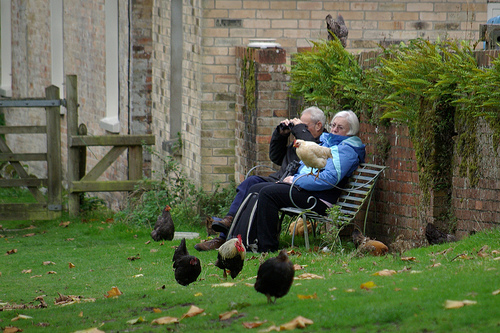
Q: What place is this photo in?
A: It is at the farm.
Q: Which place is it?
A: It is a farm.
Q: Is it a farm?
A: Yes, it is a farm.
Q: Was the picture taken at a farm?
A: Yes, it was taken in a farm.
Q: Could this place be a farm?
A: Yes, it is a farm.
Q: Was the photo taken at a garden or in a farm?
A: It was taken at a farm.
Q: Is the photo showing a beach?
A: No, the picture is showing a farm.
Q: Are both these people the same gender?
A: No, they are both male and female.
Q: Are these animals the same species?
A: Yes, all the animals are chicken.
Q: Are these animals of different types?
A: No, all the animals are chicken.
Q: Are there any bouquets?
A: No, there are no bouquets.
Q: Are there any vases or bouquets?
A: No, there are no bouquets or vases.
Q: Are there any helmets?
A: No, there are no helmets.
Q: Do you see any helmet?
A: No, there are no helmets.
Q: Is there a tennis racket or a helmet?
A: No, there are no helmets or rackets.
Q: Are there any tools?
A: No, there are no tools.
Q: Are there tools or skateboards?
A: No, there are no tools or skateboards.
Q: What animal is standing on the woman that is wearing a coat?
A: The chicken is standing on the woman.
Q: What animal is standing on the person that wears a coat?
A: The chicken is standing on the woman.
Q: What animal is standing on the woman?
A: The chicken is standing on the woman.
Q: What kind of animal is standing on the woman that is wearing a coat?
A: The animal is chicken.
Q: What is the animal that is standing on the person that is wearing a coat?
A: The animal is chicken.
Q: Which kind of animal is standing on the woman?
A: The animal is chicken.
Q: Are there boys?
A: No, there are no boys.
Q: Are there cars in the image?
A: No, there are no cars.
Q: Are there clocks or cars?
A: No, there are no cars or clocks.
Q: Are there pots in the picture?
A: No, there are no pots.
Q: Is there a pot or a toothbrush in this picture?
A: No, there are no pots or toothbrushes.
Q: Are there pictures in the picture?
A: No, there are no pictures.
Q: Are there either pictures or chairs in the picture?
A: No, there are no pictures or chairs.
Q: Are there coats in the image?
A: Yes, there is a coat.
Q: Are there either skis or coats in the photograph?
A: Yes, there is a coat.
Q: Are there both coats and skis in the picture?
A: No, there is a coat but no skis.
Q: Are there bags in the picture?
A: No, there are no bags.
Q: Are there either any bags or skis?
A: No, there are no bags or skis.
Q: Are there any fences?
A: Yes, there is a fence.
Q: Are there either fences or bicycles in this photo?
A: Yes, there is a fence.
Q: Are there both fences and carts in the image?
A: No, there is a fence but no carts.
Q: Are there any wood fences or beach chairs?
A: Yes, there is a wood fence.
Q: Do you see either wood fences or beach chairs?
A: Yes, there is a wood fence.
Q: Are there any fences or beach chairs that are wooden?
A: Yes, the fence is wooden.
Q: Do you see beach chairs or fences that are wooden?
A: Yes, the fence is wooden.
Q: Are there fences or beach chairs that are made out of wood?
A: Yes, the fence is made of wood.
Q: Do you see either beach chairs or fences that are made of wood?
A: Yes, the fence is made of wood.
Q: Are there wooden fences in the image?
A: Yes, there is a wood fence.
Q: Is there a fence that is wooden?
A: Yes, there is a fence that is wooden.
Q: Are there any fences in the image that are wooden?
A: Yes, there is a fence that is wooden.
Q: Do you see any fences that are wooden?
A: Yes, there is a fence that is wooden.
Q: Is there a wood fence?
A: Yes, there is a fence that is made of wood.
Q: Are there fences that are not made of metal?
A: Yes, there is a fence that is made of wood.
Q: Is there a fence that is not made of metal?
A: Yes, there is a fence that is made of wood.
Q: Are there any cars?
A: No, there are no cars.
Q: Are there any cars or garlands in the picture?
A: No, there are no cars or garlands.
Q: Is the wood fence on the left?
A: Yes, the fence is on the left of the image.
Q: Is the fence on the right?
A: No, the fence is on the left of the image.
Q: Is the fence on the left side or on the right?
A: The fence is on the left of the image.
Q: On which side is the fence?
A: The fence is on the left of the image.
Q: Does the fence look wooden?
A: Yes, the fence is wooden.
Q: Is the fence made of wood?
A: Yes, the fence is made of wood.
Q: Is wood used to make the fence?
A: Yes, the fence is made of wood.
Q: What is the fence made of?
A: The fence is made of wood.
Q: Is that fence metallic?
A: No, the fence is wooden.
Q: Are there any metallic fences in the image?
A: No, there is a fence but it is wooden.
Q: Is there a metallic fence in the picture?
A: No, there is a fence but it is wooden.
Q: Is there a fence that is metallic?
A: No, there is a fence but it is wooden.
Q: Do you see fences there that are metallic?
A: No, there is a fence but it is wooden.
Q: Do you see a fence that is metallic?
A: No, there is a fence but it is wooden.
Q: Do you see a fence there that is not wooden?
A: No, there is a fence but it is wooden.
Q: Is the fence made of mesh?
A: No, the fence is made of wood.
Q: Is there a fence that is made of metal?
A: No, there is a fence but it is made of wood.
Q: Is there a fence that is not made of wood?
A: No, there is a fence but it is made of wood.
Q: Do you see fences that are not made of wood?
A: No, there is a fence but it is made of wood.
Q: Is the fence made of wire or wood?
A: The fence is made of wood.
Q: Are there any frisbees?
A: No, there are no frisbees.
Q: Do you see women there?
A: Yes, there is a woman.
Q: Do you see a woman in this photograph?
A: Yes, there is a woman.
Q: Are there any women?
A: Yes, there is a woman.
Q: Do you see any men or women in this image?
A: Yes, there is a woman.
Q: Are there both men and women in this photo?
A: Yes, there are both a woman and a man.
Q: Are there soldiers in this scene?
A: No, there are no soldiers.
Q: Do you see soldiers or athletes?
A: No, there are no soldiers or athletes.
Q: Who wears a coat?
A: The woman wears a coat.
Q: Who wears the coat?
A: The woman wears a coat.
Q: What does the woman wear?
A: The woman wears a coat.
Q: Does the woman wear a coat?
A: Yes, the woman wears a coat.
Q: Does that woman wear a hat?
A: No, the woman wears a coat.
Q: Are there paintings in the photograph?
A: No, there are no paintings.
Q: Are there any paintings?
A: No, there are no paintings.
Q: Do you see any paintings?
A: No, there are no paintings.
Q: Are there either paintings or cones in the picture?
A: No, there are no paintings or cones.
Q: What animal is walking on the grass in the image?
A: The chicken is walking on the grass.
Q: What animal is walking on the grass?
A: The chicken is walking on the grass.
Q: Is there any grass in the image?
A: Yes, there is grass.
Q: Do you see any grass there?
A: Yes, there is grass.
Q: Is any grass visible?
A: Yes, there is grass.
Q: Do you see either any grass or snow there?
A: Yes, there is grass.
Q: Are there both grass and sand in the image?
A: No, there is grass but no sand.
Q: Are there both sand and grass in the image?
A: No, there is grass but no sand.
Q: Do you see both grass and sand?
A: No, there is grass but no sand.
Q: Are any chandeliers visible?
A: No, there are no chandeliers.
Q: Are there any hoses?
A: No, there are no hoses.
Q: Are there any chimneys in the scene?
A: No, there are no chimneys.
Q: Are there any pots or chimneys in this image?
A: No, there are no chimneys or pots.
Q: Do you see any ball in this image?
A: No, there are no balls.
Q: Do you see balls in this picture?
A: No, there are no balls.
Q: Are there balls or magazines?
A: No, there are no balls or magazines.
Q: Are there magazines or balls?
A: No, there are no balls or magazines.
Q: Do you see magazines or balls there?
A: No, there are no balls or magazines.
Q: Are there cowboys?
A: No, there are no cowboys.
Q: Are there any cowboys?
A: No, there are no cowboys.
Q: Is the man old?
A: Yes, the man is old.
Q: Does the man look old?
A: Yes, the man is old.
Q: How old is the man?
A: The man is old.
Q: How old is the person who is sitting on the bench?
A: The man is old.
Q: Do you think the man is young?
A: No, the man is old.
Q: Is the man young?
A: No, the man is old.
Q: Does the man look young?
A: No, the man is old.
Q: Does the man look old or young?
A: The man is old.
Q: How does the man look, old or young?
A: The man is old.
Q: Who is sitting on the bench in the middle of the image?
A: The man is sitting on the bench.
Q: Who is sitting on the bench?
A: The man is sitting on the bench.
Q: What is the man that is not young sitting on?
A: The man is sitting on the bench.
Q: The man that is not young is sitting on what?
A: The man is sitting on the bench.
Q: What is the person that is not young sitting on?
A: The man is sitting on the bench.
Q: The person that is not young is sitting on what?
A: The man is sitting on the bench.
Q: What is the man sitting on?
A: The man is sitting on the bench.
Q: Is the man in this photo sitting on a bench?
A: Yes, the man is sitting on a bench.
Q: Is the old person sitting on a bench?
A: Yes, the man is sitting on a bench.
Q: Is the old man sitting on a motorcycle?
A: No, the man is sitting on a bench.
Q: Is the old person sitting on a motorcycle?
A: No, the man is sitting on a bench.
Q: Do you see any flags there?
A: No, there are no flags.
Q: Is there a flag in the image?
A: No, there are no flags.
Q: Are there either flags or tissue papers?
A: No, there are no flags or tissue papers.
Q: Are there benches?
A: Yes, there is a bench.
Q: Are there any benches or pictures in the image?
A: Yes, there is a bench.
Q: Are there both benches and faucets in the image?
A: No, there is a bench but no faucets.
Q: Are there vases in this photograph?
A: No, there are no vases.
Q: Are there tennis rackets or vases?
A: No, there are no vases or tennis rackets.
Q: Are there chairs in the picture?
A: No, there are no chairs.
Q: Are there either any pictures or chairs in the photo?
A: No, there are no chairs or pictures.